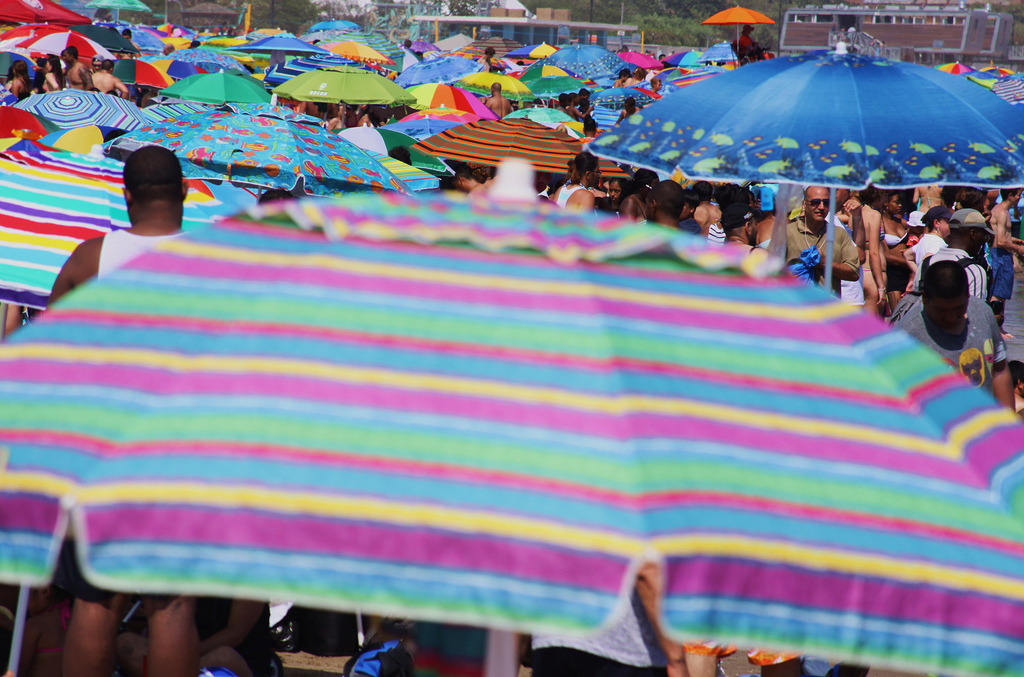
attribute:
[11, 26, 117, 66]
umbrella — red, white, pinwheel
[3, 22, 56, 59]
umbrella — red, white, pinwheel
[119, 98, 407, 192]
fish pattern — multi-colored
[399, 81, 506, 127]
umbrella — Rainbow colored